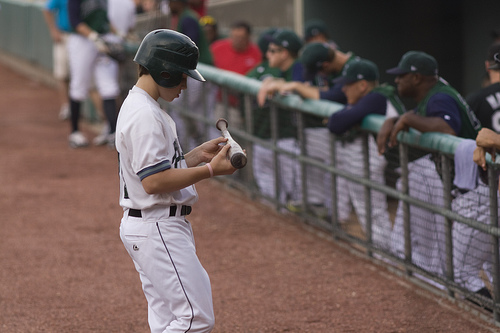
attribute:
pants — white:
[119, 209, 211, 331]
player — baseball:
[94, 57, 239, 322]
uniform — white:
[46, 94, 291, 246]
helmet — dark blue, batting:
[124, 23, 246, 81]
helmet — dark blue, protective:
[126, 22, 209, 97]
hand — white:
[211, 144, 251, 183]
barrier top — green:
[204, 63, 498, 169]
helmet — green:
[130, 17, 214, 98]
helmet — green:
[131, 22, 206, 94]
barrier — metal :
[93, 50, 498, 310]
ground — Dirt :
[233, 197, 308, 276]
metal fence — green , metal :
[0, 0, 499, 330]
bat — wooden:
[215, 116, 247, 168]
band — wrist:
[203, 156, 221, 185]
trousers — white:
[152, 216, 188, 328]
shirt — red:
[203, 45, 267, 95]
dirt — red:
[191, 197, 386, 317]